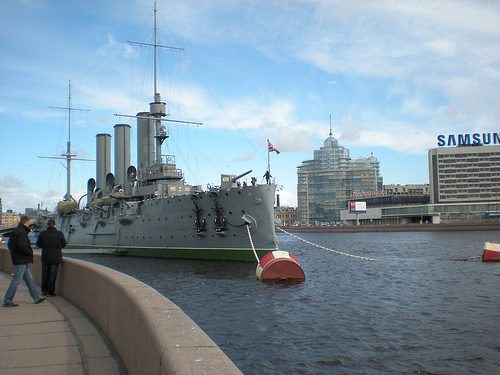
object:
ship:
[32, 39, 277, 266]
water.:
[205, 234, 497, 374]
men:
[6, 213, 66, 304]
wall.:
[66, 258, 165, 367]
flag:
[267, 138, 279, 157]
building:
[427, 146, 500, 224]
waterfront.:
[279, 220, 499, 234]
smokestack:
[111, 124, 133, 188]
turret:
[218, 169, 256, 183]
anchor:
[190, 200, 207, 235]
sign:
[345, 199, 367, 212]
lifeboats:
[58, 199, 81, 215]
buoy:
[253, 248, 308, 283]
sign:
[434, 132, 500, 145]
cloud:
[208, 101, 300, 140]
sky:
[0, 2, 492, 136]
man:
[34, 226, 67, 293]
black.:
[44, 234, 61, 245]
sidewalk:
[3, 309, 92, 371]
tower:
[149, 85, 187, 177]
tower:
[48, 141, 84, 206]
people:
[225, 172, 272, 185]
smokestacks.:
[93, 132, 114, 200]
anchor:
[208, 198, 229, 234]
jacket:
[37, 230, 68, 260]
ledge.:
[62, 252, 234, 373]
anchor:
[481, 240, 498, 262]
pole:
[267, 150, 271, 175]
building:
[295, 114, 381, 221]